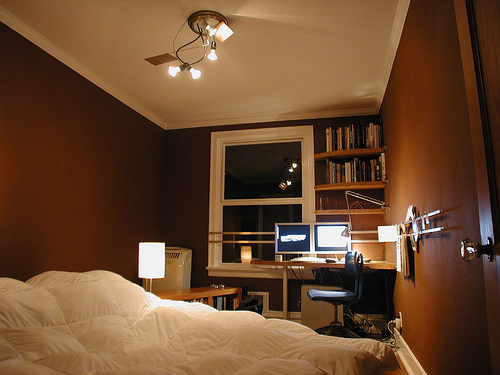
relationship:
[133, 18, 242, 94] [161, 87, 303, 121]
lights hanging from ceiling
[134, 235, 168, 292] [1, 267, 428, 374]
lamp next to bed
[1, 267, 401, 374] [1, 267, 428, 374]
comforter on bed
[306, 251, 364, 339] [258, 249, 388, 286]
chair in front of desk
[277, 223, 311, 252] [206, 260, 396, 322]
monitor on desk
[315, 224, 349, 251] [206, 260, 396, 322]
monitor on desk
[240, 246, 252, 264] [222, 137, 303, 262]
candle in window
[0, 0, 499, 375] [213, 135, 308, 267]
bedroom in window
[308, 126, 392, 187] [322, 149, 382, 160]
books on bookshelf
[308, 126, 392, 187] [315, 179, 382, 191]
books on bookshelf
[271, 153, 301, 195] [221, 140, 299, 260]
light reflecting in glass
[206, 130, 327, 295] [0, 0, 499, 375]
window in bedroom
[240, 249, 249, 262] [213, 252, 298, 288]
candle on sill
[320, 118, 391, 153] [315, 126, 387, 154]
books on top of shelf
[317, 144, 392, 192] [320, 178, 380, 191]
books on shelf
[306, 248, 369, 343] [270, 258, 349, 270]
chair in front of desk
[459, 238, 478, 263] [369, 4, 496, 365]
door knob on door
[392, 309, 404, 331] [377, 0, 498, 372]
electrical socket on wall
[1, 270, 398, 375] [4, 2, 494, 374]
comforter in room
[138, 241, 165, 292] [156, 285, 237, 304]
lamp beside table